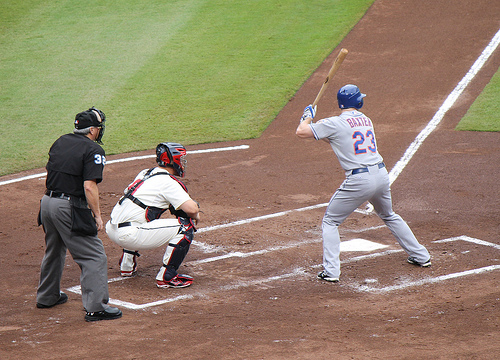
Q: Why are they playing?
A: Baseball.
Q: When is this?
A: Daytime.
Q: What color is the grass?
A: Green.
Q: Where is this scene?
A: At a baseball park.